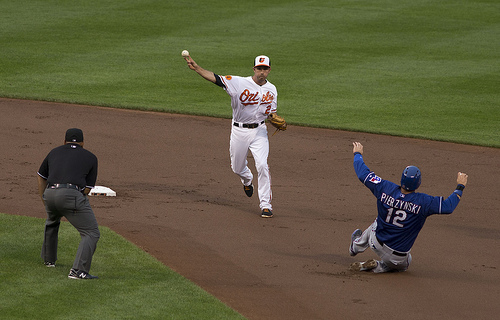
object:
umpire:
[23, 123, 135, 284]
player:
[184, 54, 287, 219]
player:
[347, 139, 468, 274]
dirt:
[122, 135, 257, 264]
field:
[0, 0, 497, 318]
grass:
[0, 0, 499, 147]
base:
[82, 184, 120, 199]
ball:
[178, 50, 190, 60]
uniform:
[211, 70, 280, 208]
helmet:
[400, 164, 422, 193]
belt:
[228, 118, 266, 132]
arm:
[193, 67, 231, 91]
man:
[180, 51, 279, 219]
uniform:
[347, 152, 463, 273]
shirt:
[37, 140, 103, 189]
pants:
[33, 187, 101, 273]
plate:
[87, 184, 117, 198]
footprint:
[321, 262, 373, 284]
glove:
[262, 112, 290, 132]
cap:
[253, 54, 273, 70]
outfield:
[0, 0, 499, 145]